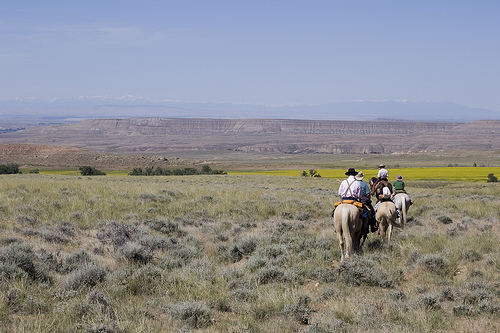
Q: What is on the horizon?
A: Mountains.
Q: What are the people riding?
A: Horses.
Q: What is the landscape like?
A: Lots of brush and few trees.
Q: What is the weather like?
A: Sunny.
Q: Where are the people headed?
A: Away from the camera.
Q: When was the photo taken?
A: Daytime.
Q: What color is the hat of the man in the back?
A: Black.